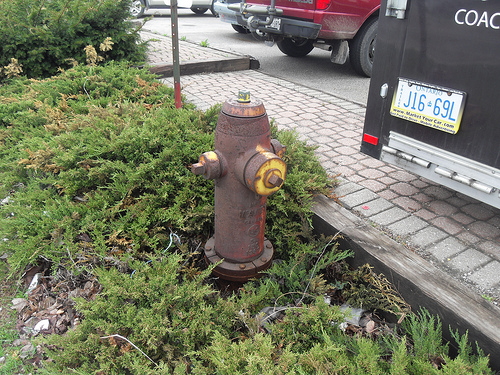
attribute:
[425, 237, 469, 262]
brick — gray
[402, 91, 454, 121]
letters — blue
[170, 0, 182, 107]
post — red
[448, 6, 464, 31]
letter — white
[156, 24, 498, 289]
brick — gray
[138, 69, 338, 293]
hydrant — yellow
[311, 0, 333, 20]
tail light — red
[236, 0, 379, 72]
truck — red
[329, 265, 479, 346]
log — wooden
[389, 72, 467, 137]
license plate — rectangular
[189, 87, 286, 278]
hydrant — fire, fire hydrant, rusty, faded, gray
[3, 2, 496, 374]
shrubs — green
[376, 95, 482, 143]
plate — white, license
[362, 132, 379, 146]
brake light — red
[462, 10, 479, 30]
letter — white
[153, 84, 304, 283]
hydrant — rusty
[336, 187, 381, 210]
brick — gray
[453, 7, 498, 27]
letters — white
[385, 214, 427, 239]
brick — gray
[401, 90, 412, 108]
letter — blue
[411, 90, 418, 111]
letter — blue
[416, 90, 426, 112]
letter — blue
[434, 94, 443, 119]
letter — blue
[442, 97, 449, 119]
letter — blue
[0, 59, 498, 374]
bushes — green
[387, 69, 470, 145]
license plate — white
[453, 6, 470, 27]
letter — white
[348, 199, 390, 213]
brick — gray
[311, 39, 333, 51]
exhaust — dark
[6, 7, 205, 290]
bushes — green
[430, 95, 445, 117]
number — blue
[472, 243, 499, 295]
brick — gray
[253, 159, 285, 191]
cap — yellow